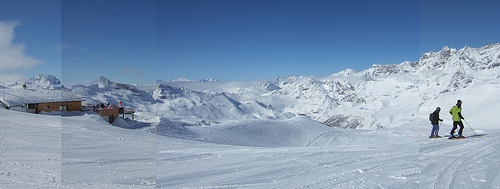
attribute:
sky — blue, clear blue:
[2, 2, 500, 84]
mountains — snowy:
[1, 42, 500, 129]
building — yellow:
[1, 91, 121, 121]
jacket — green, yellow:
[449, 106, 464, 126]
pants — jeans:
[432, 125, 441, 142]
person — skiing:
[446, 96, 467, 143]